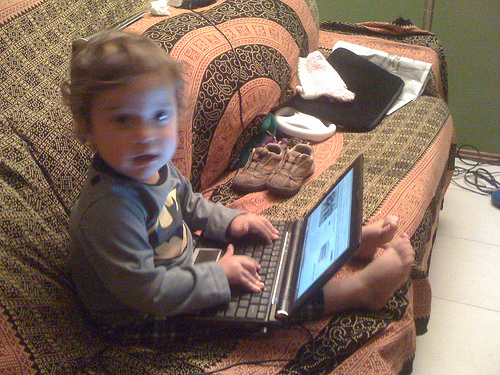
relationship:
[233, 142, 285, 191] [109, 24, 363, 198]
shoe on couch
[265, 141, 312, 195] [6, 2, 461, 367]
shoe on couch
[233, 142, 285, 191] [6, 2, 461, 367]
shoe on couch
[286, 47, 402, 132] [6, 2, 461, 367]
cover on couch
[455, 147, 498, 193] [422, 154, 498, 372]
cords on floor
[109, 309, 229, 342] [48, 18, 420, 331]
pants on kid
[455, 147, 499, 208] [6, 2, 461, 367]
cords on couch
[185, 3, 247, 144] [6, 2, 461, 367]
power cord on couch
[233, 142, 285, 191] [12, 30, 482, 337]
shoe on sofa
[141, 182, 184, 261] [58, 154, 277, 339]
logo on shirt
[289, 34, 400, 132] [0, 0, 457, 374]
case on couch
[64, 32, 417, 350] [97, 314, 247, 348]
boy wearing pants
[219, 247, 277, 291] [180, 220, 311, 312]
keys on keyboard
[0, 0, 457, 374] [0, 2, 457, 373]
couch swathed cover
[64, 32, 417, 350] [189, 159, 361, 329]
boy working on laptop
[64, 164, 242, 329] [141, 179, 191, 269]
shirt has symbol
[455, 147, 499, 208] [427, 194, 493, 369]
cords on floor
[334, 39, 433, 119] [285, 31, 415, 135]
newspaper under pillow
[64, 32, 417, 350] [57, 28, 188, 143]
boy has hair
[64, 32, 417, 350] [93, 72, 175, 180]
boy has face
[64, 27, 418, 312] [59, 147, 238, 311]
boy wearing shirt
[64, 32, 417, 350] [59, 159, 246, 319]
boy wearing shirt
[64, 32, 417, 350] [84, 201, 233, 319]
boy wearing shirt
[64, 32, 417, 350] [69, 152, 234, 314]
boy wearing shirt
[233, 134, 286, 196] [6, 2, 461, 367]
shoe on couch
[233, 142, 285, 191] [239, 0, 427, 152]
shoe on couch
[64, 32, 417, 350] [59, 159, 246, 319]
boy wearing a shirt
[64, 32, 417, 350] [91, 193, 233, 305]
boy wearing a shirt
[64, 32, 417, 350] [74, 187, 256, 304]
boy wearing a shirt